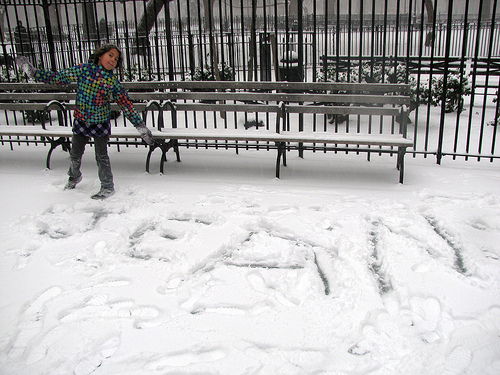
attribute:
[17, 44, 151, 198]
girl — little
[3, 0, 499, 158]
fence — wire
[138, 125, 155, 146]
glove — gray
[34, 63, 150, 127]
jacket — colorful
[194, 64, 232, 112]
bush — green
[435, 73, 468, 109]
bush — green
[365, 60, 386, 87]
bush — green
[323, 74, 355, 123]
bush — green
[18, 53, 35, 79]
glove — gray